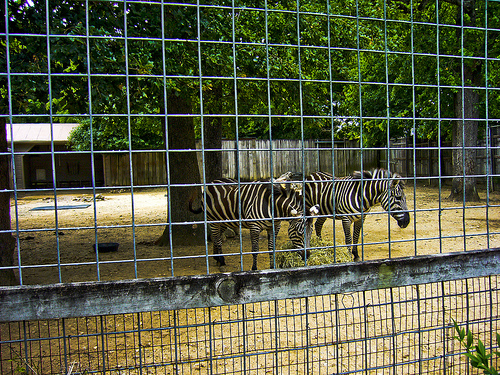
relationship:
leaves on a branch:
[237, 26, 279, 70] [159, 79, 197, 107]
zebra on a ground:
[188, 172, 336, 275] [192, 264, 403, 347]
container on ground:
[92, 237, 121, 253] [192, 264, 403, 347]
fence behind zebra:
[4, 1, 495, 160] [188, 172, 336, 275]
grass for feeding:
[281, 244, 358, 274] [291, 243, 315, 261]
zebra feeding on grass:
[188, 172, 336, 275] [281, 244, 358, 274]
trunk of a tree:
[160, 178, 217, 249] [103, 7, 215, 145]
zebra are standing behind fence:
[188, 172, 336, 275] [4, 1, 495, 160]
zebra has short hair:
[188, 172, 336, 275] [250, 176, 303, 202]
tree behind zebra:
[103, 7, 215, 145] [188, 172, 336, 275]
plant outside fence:
[448, 309, 500, 373] [4, 1, 495, 160]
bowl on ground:
[92, 237, 121, 253] [192, 264, 403, 347]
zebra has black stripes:
[301, 160, 421, 266] [331, 179, 360, 208]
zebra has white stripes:
[188, 172, 336, 275] [210, 191, 228, 207]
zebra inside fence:
[188, 172, 336, 275] [4, 1, 495, 160]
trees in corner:
[365, 23, 496, 176] [478, 25, 500, 117]